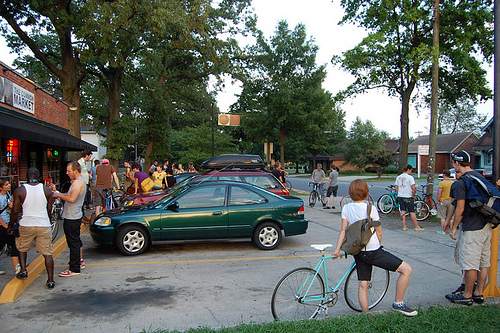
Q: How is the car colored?
A: Green.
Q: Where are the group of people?
A: Outside the store.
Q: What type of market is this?
A: Local market.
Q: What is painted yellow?
A: Curb.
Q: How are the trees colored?
A: Green.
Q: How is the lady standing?
A: One foot on curb.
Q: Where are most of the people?
A: Next to the building.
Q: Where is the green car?
A: Parked next to the building.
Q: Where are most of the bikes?
A: Next to the tree.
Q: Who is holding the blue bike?
A: A young woman with a message bag.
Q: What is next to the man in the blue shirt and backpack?
A: A yellow pole.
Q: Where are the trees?
A: Along the street.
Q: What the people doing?
A: Talking.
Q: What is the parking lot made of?
A: Asphalt.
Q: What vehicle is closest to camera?
A: Green car.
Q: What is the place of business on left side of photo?
A: Market.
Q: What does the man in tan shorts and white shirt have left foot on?
A: Curb.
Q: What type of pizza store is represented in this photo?
A: Domino's.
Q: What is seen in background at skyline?
A: Trees.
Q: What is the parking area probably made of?
A: Asphalt.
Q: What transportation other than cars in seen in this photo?
A: Bicycles.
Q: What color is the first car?
A: Green.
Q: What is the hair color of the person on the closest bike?
A: Red.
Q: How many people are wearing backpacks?
A: 3.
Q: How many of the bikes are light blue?
A: 2.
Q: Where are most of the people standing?
A: By the market.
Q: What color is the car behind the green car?
A: Dark red.